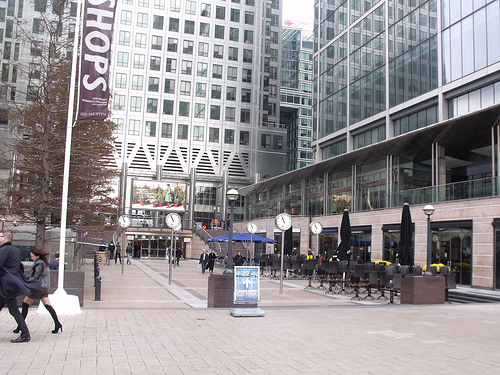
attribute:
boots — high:
[16, 302, 76, 339]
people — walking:
[1, 228, 66, 342]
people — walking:
[195, 247, 215, 274]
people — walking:
[97, 238, 136, 266]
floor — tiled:
[82, 318, 494, 373]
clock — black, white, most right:
[161, 210, 190, 232]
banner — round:
[59, 0, 124, 134]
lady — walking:
[23, 245, 73, 340]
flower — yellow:
[422, 260, 454, 291]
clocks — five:
[174, 190, 336, 240]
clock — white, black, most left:
[260, 207, 320, 243]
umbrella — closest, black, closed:
[393, 199, 417, 264]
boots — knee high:
[15, 301, 66, 335]